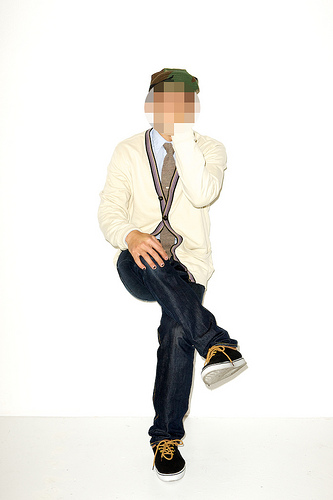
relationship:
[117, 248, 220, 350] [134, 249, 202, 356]
leg crossed at knee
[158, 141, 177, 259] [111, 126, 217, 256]
hanging tie down to torso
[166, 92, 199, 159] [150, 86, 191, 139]
hand lifted to face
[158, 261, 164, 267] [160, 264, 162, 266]
nail has polish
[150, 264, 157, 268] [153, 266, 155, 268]
nail has polish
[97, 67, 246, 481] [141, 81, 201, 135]
man has face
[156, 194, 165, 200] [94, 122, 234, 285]
button on sweater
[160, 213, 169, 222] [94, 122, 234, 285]
button on sweater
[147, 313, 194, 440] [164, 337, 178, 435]
pant leg with crease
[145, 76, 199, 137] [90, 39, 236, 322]
face of person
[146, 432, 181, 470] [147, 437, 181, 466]
black sneakers with yellow laces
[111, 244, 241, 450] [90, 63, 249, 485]
jeans on person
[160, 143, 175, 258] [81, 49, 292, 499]
hanging tie on person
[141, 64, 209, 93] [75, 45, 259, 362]
hat on person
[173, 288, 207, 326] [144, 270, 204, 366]
leg on jeans